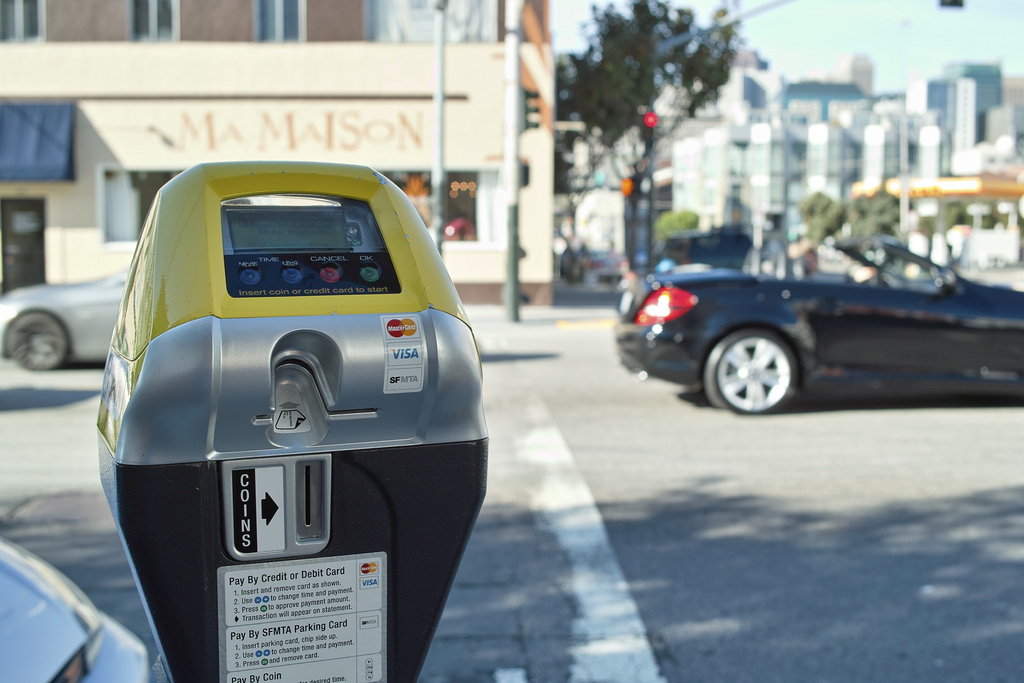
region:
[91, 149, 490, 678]
a yellow parking meter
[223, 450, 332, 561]
a coin insertion slot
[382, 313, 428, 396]
a credit card acceptance logo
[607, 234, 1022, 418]
a black convertible car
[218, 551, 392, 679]
a white instructional sticker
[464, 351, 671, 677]
a white marked pedestrian crosswalk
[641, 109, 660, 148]
a red traffic signal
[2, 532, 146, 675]
a white parked car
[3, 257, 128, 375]
a grey parked car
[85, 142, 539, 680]
yellow and black parking meter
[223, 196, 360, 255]
display on the parking meter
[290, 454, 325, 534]
coin slot on the parking meter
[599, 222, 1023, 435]
dark colored convertable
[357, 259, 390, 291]
green button on the meter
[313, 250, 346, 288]
red button on the meter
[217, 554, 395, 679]
instructions on the meter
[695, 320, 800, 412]
back wheel on the convertable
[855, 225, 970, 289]
windshield on the convertable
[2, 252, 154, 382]
car behind the parking meter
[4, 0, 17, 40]
a window on a building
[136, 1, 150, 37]
a window on a building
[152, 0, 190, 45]
a window on a building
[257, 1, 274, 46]
a window on a building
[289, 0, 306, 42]
a window on a building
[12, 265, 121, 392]
a car on a street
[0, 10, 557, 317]
a building in a city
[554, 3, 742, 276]
a tree in a city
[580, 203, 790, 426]
back of the car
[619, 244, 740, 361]
light on back of car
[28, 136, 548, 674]
meter next to street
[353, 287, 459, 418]
logo on the meter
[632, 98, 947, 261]
blurry buildings in distance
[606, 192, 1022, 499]
dark car on street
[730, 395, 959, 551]
light hitting the street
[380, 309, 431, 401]
credit card logos on the meter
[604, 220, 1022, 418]
sports car in the parking lot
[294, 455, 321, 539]
coin slot on the meter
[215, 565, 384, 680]
instructions for the meter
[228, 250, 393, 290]
buttons on the meter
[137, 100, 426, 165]
letters on the store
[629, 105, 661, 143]
red traffic light on the sidewalk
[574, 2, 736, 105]
tree behind the traffic light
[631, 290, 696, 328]
red backlight on the car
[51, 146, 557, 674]
The black and yellow parking meter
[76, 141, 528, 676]
A black and yellow parking meter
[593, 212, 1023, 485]
The black vehicle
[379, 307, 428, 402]
logos to represent payments accepted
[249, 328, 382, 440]
credit card slot on parking meter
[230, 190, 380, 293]
digital display on parking meter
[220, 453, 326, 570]
coin slot on parking meter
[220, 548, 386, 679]
directions on how to use parking meter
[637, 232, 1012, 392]
black convertible sportscar driven by old white man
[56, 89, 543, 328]
boutique on street corner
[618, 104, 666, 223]
traffic and pedestrian lights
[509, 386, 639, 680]
worn white stripe on street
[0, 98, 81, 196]
blue awning on the building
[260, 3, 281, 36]
building has a window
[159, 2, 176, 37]
building has a window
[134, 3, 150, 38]
building has a window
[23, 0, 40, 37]
building has a window